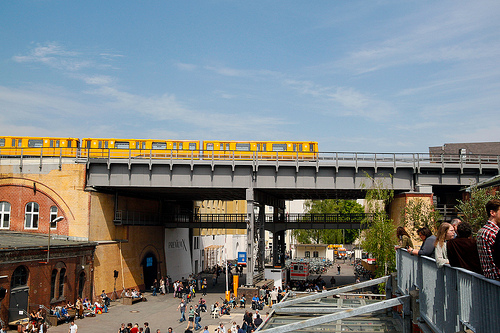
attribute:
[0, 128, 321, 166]
train — yellow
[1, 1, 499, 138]
sky — blue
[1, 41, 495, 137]
clouds — white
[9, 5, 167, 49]
sky — blue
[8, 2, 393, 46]
sky — blue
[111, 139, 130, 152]
window — small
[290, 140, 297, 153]
window — yellow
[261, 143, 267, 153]
window — small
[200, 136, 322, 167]
cart — yellow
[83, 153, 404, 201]
bridge — gray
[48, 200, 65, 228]
window — broken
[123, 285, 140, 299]
people — sitting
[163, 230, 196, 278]
wall — white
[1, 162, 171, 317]
building — tan, brown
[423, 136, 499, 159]
building — brown